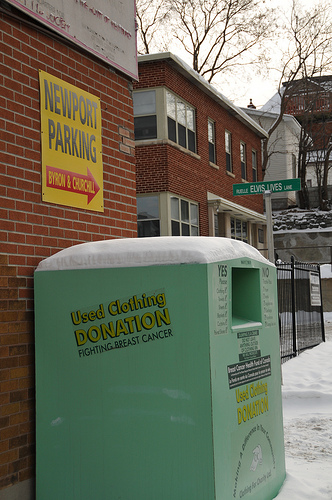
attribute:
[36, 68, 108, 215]
sign — giving, black, yellow, for parking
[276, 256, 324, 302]
fence — black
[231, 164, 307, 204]
sign — green, street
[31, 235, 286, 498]
box — donation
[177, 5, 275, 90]
trees — bare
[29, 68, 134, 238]
sign — green, on corner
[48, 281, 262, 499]
green bin — color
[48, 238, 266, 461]
donation bin — green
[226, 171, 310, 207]
street sign — green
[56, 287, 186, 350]
letters — yellow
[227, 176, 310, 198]
street sign — white, green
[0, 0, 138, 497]
brick building — bricked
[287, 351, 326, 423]
snow — white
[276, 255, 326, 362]
fence — metal, black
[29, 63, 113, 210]
sign — yellow, parking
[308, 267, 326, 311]
sign — attached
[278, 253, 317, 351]
gate — security, black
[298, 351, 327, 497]
area — covered